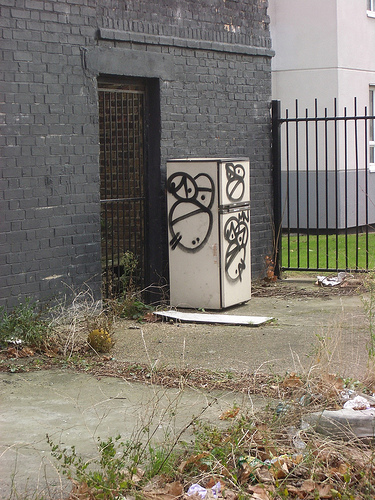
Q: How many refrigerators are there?
A: One.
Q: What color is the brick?
A: Gray.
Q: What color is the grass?
A: Green.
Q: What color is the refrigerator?
A: White.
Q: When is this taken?
A: During the daytime.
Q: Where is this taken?
A: Outside in an alley.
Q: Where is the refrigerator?
A: Against the wall.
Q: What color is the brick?
A: Black.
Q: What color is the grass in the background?
A: Green.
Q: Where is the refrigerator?
A: Near the doorway of the black building.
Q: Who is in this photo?
A: No one.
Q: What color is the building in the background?
A: White and gray.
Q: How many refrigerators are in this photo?
A: One.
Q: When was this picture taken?
A: During the day.